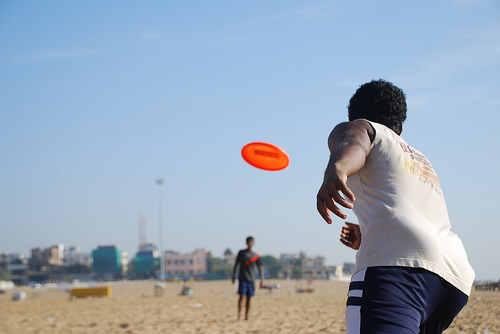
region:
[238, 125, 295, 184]
the frisbee is orange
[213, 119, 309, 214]
the frisbee is orange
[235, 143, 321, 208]
the frisbee is orange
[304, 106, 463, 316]
the shirt is white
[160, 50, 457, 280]
a man tossing a frisbee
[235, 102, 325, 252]
a orange frisbee in the air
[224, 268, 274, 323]
a boy wearing blue shorts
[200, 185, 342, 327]
a man standing on sand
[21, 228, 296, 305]
lots of buildings in the back ground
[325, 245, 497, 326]
blue shorts with a white stripe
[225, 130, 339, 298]
a man waiting on a frisbee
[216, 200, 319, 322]
a man with a dark grey shirt on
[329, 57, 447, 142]
the back of a man head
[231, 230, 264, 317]
Man standing in the sand.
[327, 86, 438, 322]
Man lunging in the sand.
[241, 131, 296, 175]
Red Frisbee in the air.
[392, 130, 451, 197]
Big orange letters on back of shirt.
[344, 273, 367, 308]
Blue and white stripes on man's shorts.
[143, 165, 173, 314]
Long pole in the stand.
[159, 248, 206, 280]
Pink building in the distance.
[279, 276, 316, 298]
People sitting down in the dirt.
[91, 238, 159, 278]
Two blue buildings to the right.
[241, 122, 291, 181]
an orange freezbee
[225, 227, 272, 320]
a man wearing a grey shirt with a red strip and blue shorts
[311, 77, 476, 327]
a man leaning forward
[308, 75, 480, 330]
a man wearing a white shirt and blue shorts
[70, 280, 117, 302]
a yellow box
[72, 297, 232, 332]
beach sand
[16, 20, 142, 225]
a blue sky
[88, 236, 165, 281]
two blue and green buildings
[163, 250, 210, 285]
a pink building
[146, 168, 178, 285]
a white pole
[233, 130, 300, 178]
An orange frisbee is in the air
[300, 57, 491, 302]
The man has a white shirt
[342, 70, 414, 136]
The man has black hair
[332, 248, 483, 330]
The man has blue shorts with white markings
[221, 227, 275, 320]
The man waits to catch the frisbee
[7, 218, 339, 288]
Buildings are in the distance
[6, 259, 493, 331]
A sandy beach provides the landscape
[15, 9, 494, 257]
The sky is hazy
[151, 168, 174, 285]
A pole stands in the distance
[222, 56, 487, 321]
A frisbee is thrown